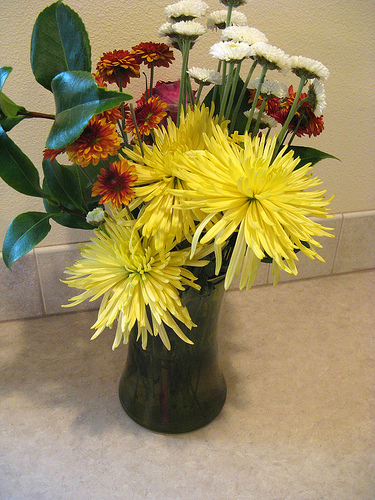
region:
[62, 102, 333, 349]
Yellow flowers in the vase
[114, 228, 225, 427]
Transparent vase on the ground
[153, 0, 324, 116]
White flowers in the vase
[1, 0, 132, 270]
Green leaves near the yellow flower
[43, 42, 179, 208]
Red flowers in the vase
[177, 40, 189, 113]
Green stem of the white flower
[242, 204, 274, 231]
Yellow petals of the yellow flowers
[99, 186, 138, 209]
Red petals of the red flower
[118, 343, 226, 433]
Water inside the vase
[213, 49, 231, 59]
White petals on the white flower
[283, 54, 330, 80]
flower in the vase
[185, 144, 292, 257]
flower in the vase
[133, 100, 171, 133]
flower in the vase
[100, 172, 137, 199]
flower in the vase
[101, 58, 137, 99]
flower in the vase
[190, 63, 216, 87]
flower in the vase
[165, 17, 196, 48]
flower in the vase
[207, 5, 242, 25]
flower in the vase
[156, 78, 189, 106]
flower in the vase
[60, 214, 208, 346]
Yellow flower with long thin petals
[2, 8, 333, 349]
Floral arrangement in glass vase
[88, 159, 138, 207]
Small orange multi petaled flower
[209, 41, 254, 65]
Small white opened flower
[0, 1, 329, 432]
Assorted live flowers in green vase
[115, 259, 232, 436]
Clear green glass vase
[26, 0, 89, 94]
Shiny dark green leaf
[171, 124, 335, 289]
Pale yellow light fluffy flower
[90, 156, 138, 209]
Orange flower with short tight petals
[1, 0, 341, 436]
Glass vase holding yellow orange and white flowers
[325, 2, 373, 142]
wall painted white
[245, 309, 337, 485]
floor made of granite for walking on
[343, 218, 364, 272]
bottom layer of wall made from tiles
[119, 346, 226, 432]
clear vase for flowers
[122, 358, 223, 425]
vase filled with water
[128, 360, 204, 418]
bottom of vase with flower stems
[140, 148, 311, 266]
large yellow flowers with long stems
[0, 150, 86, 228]
large shiny leaves of plants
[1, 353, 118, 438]
shadow of flowers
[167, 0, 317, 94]
smaller flowers with yellow petals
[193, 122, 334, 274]
a yellow flower in a vase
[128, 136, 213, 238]
a yellow flower in a vase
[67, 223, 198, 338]
a yellow flower in a vase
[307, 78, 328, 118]
a white flower in a vase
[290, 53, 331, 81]
a white flower in a vase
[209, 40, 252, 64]
a white flower in a vase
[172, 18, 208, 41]
a white flower in a vase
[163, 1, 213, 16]
a white flower in a vase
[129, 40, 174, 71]
a red and orange flower in a vase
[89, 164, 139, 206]
a red and orange flower in a vase